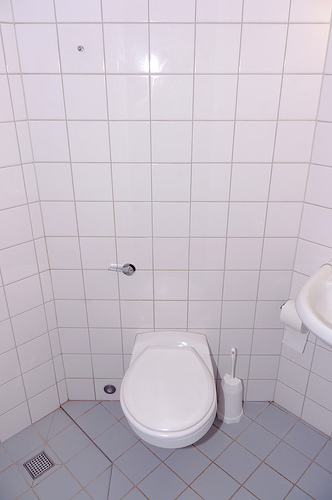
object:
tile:
[150, 25, 193, 77]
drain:
[22, 449, 56, 475]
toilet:
[120, 331, 217, 450]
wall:
[7, 0, 326, 411]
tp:
[278, 300, 310, 359]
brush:
[229, 345, 240, 377]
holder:
[215, 371, 244, 424]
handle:
[106, 263, 136, 277]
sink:
[294, 264, 332, 349]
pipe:
[101, 383, 118, 395]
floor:
[3, 400, 330, 498]